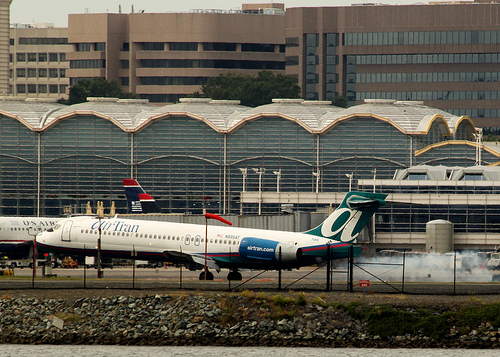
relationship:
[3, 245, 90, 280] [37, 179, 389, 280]
cart at airplane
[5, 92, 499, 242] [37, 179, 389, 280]
airplane terminal behind airplane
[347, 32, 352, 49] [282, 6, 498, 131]
window on building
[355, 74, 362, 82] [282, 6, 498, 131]
window on building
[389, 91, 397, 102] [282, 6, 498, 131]
window on building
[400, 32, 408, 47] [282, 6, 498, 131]
window on building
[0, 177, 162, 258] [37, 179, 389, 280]
airplane behind airplane